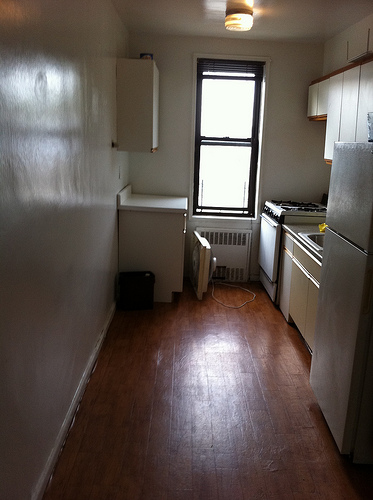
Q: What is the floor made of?
A: Wood.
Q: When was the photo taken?
A: Daytime.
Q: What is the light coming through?
A: Window.